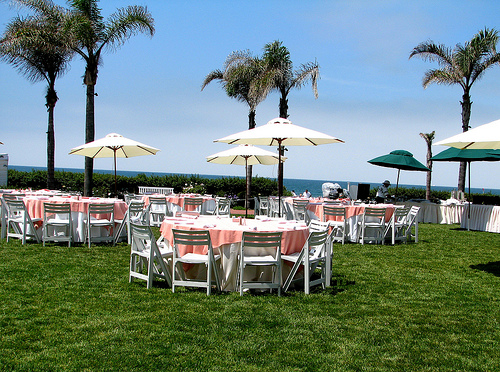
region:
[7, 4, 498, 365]
Tables are ranged outside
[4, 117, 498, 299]
Reception outdoors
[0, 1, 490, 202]
Five palms near reception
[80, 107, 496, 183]
Yellow and Green parasols covering the tabels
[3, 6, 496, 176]
Sky is blue with some clouds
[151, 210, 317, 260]
Orange tablecloth on table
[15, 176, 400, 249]
Orange tablecloths covering tables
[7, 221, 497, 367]
Tables on grass on green grass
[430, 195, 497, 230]
White tablecloth covering a table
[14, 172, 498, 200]
Ocean in the horizont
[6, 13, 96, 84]
Green top of a palm tree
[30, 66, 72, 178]
Brown trunk of a palm tree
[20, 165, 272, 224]
bushes next to tables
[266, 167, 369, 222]
blue water in the background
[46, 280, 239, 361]
green grass on the ground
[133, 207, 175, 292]
White chair at a table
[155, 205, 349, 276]
table with a pink table cloth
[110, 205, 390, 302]
table with chairs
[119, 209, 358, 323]
round table with white chairs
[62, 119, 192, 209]
beige sun umbrella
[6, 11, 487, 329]
Several tables that have been decorated.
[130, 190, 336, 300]
White folding chairs surround the table.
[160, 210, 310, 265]
The table has a pink tablecloth on it.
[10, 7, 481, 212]
Slender palm trees in the background.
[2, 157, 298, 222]
A hedge is behind the palm trees.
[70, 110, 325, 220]
Large white umbrellas.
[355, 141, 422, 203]
A worker under the green umbrella.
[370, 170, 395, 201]
The worker is setting up a table.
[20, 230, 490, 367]
Neatly kept grass.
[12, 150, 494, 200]
The ocean in the distance.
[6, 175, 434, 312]
a group of tables and chairs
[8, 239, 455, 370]
cut green grass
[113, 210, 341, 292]
white folding chairs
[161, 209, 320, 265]
pink and white table cloth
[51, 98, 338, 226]
three white table umbrellas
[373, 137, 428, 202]
a green table umbrella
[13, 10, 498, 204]
the ocean behind the palm trees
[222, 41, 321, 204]
two dried out palm trees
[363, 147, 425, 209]
a person under the green umbrella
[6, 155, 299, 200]
a line of cut green hedges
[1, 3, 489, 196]
Five palms near the beach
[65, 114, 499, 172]
Four white parasols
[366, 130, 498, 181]
Two green parasols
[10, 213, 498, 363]
Green grass on field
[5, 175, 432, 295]
Tables are arranged for a reception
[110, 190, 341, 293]
Chairs are around table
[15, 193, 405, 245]
Tables are covered with peach tablecoats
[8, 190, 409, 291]
White tablecoats cover tables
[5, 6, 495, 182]
Sky is blue with some clouds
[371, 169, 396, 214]
A person under green parasol